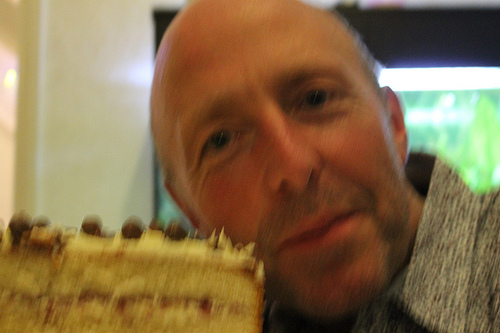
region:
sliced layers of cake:
[1, 213, 263, 328]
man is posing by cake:
[151, 0, 499, 331]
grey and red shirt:
[239, 151, 499, 331]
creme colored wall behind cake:
[1, 0, 499, 232]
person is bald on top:
[146, 0, 413, 321]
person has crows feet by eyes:
[180, 83, 370, 197]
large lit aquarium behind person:
[153, 63, 497, 242]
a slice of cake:
[0, 213, 267, 332]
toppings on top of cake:
[0, 211, 255, 256]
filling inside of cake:
[0, 290, 247, 315]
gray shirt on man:
[260, 153, 498, 331]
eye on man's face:
[193, 123, 243, 161]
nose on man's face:
[265, 103, 322, 195]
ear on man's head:
[378, 84, 407, 163]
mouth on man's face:
[272, 205, 359, 250]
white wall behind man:
[1, 0, 154, 227]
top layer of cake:
[0, 249, 259, 299]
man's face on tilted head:
[149, 1, 411, 327]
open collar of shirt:
[262, 149, 497, 331]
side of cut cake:
[2, 213, 260, 330]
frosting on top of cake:
[0, 227, 258, 259]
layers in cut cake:
[0, 262, 252, 331]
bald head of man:
[147, 0, 331, 184]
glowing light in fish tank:
[384, 66, 497, 188]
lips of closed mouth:
[279, 207, 359, 251]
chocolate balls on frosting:
[80, 215, 188, 238]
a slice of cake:
[25, 197, 279, 330]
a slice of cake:
[11, 192, 293, 329]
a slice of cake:
[2, 191, 260, 320]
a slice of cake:
[25, 206, 266, 328]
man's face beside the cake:
[125, 34, 408, 330]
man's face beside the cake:
[94, 25, 401, 325]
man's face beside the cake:
[83, 30, 413, 324]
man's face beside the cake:
[92, 63, 393, 331]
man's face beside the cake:
[83, 48, 402, 303]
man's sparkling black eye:
[279, 81, 339, 120]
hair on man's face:
[281, 260, 406, 296]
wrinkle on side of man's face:
[172, 162, 232, 197]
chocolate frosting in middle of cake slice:
[61, 278, 283, 323]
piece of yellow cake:
[94, 252, 250, 291]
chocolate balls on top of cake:
[87, 210, 187, 252]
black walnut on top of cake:
[7, 213, 51, 243]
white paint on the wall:
[45, 112, 118, 170]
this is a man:
[138, 9, 475, 330]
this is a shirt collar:
[362, 110, 491, 324]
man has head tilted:
[143, 3, 469, 325]